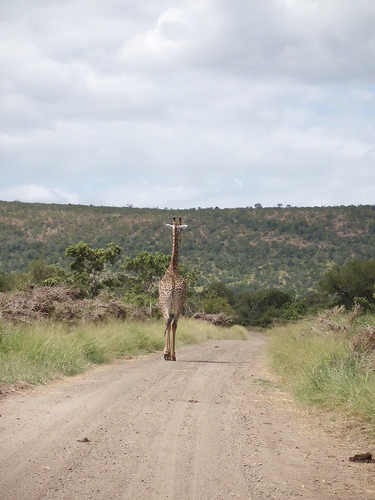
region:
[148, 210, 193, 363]
a giraffe walking down a dirt road.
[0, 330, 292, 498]
a dirt road with pebbles on it.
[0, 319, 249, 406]
a field full of grass.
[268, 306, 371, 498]
a field of lush green grass.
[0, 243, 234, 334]
a field of lush green trees.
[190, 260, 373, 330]
lots of trees at the end of a road.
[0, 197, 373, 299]
a tree covered hillside.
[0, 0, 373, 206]
a gray cloud filled sky.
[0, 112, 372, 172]
a large gray cloud.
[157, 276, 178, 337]
a giraffe tail.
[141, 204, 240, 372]
giraffe walking on dirt road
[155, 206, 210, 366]
giraffe walking down road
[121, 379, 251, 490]
dirt road in safari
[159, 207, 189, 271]
head of large giraffe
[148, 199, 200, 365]
giraffe walking in wilderness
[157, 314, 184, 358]
legs of a giraffe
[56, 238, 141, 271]
green tree shrubbery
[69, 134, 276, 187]
cloudy sky in distance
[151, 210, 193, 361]
giraffe trekking down road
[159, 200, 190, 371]
spotted animal on road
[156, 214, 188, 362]
A skinny giraffe in the middle of the road.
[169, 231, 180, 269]
The long neck of a skinny giraffe.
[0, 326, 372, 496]
A road made of dirt and rocks.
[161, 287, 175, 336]
The tail of a skinny and elegant giraffe.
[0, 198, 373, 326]
A large mountain is in the distance.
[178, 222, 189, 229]
One of the ears of an elegant giraffe.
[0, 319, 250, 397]
The wild grass on the left side of the road.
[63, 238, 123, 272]
A medium sized tree is in the distance.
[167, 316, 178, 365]
The long leg of a skinny giraffe.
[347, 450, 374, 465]
The excrement of an animal.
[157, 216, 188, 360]
A giraffe walking on the road.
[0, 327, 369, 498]
A brown dirt road.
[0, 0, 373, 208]
A gray cloudy sky.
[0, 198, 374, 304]
A mountain in the background.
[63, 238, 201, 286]
Two trees on a hill.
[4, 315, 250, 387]
Weeds on side of a road.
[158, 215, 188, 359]
A giraffe on a road.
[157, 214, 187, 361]
A giraffe on a dirt road.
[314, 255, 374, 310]
A tree on side of a road.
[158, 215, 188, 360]
A giraffe walking next to weeds.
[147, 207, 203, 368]
a giraffe walking on a road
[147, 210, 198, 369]
giraffe is tall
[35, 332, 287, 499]
road is not paved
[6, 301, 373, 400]
grass on both side of unpaved road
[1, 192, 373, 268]
a hill covered with plants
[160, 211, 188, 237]
two horns of giraffe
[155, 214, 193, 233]
ears of giraffe are on the side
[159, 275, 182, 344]
tail with turf of giraffe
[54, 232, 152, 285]
small trees on a field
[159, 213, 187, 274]
giraffe has a long neck